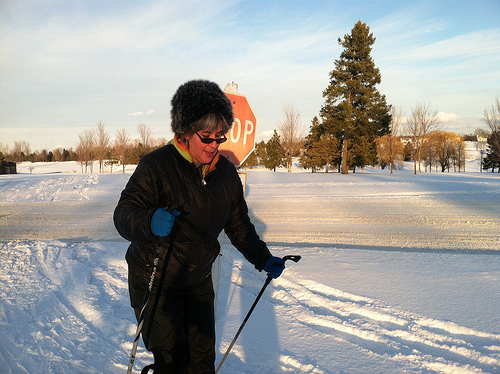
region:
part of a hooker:
[233, 280, 275, 320]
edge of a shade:
[264, 300, 286, 359]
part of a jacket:
[173, 237, 208, 319]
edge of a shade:
[268, 319, 288, 354]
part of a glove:
[262, 248, 297, 298]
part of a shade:
[249, 307, 284, 364]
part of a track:
[329, 274, 377, 330]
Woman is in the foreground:
[101, 70, 319, 372]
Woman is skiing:
[77, 84, 309, 370]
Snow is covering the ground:
[6, 178, 499, 372]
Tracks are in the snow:
[238, 252, 478, 372]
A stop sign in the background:
[218, 88, 277, 178]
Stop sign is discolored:
[223, 88, 268, 179]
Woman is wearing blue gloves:
[130, 200, 320, 290]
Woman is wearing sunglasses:
[185, 125, 245, 156]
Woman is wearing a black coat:
[108, 150, 295, 310]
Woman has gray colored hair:
[168, 105, 238, 149]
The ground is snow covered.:
[340, 248, 498, 326]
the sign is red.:
[217, 99, 285, 163]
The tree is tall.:
[310, 13, 391, 191]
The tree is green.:
[302, 23, 379, 178]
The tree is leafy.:
[310, 31, 415, 219]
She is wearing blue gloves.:
[146, 201, 197, 243]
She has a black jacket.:
[100, 136, 302, 274]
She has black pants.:
[125, 276, 247, 370]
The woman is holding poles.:
[160, 241, 361, 372]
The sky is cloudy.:
[40, 6, 160, 126]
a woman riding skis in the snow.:
[97, 88, 302, 370]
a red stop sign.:
[200, 82, 283, 174]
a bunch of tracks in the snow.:
[0, 238, 497, 371]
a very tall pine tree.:
[305, 20, 397, 177]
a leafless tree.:
[393, 93, 445, 170]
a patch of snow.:
[455, 120, 495, 175]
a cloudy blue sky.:
[0, 0, 499, 150]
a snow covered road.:
[0, 196, 498, 251]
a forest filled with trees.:
[0, 103, 496, 170]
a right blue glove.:
[145, 212, 180, 247]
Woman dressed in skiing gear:
[104, 75, 308, 372]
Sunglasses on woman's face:
[188, 122, 230, 145]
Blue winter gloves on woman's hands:
[141, 198, 290, 284]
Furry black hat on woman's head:
[166, 73, 236, 140]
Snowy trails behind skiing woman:
[4, 227, 173, 372]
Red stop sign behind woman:
[208, 72, 259, 204]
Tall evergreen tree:
[297, 13, 411, 176]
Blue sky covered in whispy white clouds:
[16, 4, 488, 143]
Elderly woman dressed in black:
[118, 73, 280, 368]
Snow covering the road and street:
[3, 152, 493, 360]